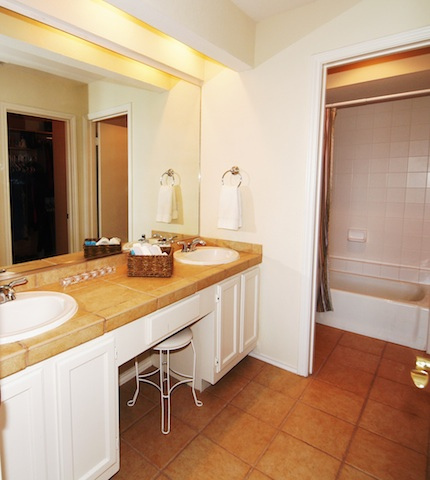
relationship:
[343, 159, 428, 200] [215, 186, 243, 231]
reflection of hand towel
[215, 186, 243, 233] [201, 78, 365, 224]
hand towel hanging wall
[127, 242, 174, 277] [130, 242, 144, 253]
basket of product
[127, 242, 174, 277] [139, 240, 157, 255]
basket of product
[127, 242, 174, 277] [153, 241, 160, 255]
basket of product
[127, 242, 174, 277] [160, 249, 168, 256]
basket of product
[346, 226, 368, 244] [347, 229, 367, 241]
place to hold soap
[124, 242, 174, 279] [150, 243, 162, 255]
basket of towel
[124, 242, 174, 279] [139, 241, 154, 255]
basket of towel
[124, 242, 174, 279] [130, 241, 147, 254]
basket of towel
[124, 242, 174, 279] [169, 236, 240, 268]
basket next to sink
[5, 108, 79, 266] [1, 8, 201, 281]
closet reflection in mirror